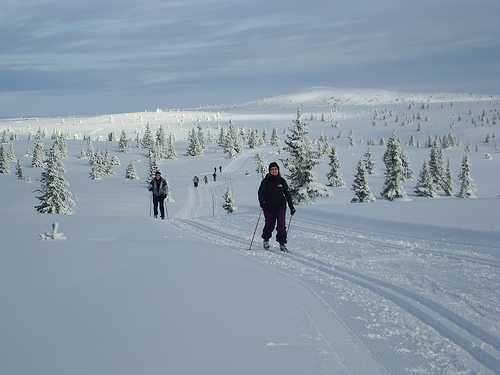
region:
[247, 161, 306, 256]
person walking on snow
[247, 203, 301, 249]
ski sticks that aid in walking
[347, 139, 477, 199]
conifers ladden with snow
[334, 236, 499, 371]
vehicle tracks made in the snow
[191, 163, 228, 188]
people in the background that have some catching up to do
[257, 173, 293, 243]
heavy layering indicates it is cold outside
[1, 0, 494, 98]
cloudy skies indicate not much sunshine is out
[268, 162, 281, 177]
smile on her face indicates happiness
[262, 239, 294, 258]
possibly skis on her feet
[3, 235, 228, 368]
patch of clean snow without marks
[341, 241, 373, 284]
part of a floor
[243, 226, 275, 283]
part of a hooker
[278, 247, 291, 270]
par tof a shoe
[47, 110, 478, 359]
two people on skis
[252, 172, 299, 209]
person wearing black jacket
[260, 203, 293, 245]
person wearing purple pants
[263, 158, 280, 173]
person wearing black hat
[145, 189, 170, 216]
person wearing black pants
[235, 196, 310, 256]
person holding ski poles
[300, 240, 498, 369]
ski tracks in snow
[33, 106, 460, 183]
trees with snow in background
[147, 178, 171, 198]
person wearing two toned top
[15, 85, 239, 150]
sun shining on snow in background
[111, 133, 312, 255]
two people on snow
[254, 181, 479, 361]
deep tracks in snow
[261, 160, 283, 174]
person has black cap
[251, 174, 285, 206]
person has black coat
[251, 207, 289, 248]
person has black pants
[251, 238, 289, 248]
person has dark shoes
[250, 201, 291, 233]
person has red ski poles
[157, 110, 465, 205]
green fir trees with snow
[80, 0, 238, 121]
dark grey and cloudy sky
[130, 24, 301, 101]
thick and heavy clouds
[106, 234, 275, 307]
Ground is white color.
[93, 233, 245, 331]
Snow is in ground.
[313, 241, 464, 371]
Marks are in snow.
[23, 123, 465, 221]
Pine trees are in ground.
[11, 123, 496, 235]
Trees are covered with snow.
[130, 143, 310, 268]
People are skiing.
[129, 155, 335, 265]
People are holding ski poles in hand.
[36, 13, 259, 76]
Sky is blue color.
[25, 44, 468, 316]
Day time picture.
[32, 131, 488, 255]
Shadow falls on snow.